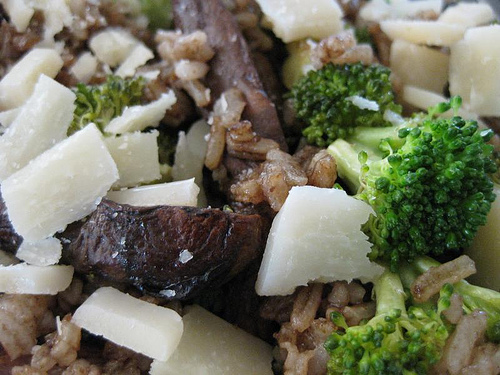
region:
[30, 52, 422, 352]
white chunks of food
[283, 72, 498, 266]
a piece of broccoli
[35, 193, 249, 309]
a piece of cooked meat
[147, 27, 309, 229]
pieces of brown rice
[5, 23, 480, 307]
a rice, meat and veggie dish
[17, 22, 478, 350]
food mixed together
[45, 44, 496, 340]
veggies and meat mixed together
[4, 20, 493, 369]
a rice dish with meat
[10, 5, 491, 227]
a rice dish with broccoli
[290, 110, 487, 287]
dark green cooked broccoli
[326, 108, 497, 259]
Whole peice of broccolli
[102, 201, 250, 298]
Peice of a mushroom top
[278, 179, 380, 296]
A peice of something white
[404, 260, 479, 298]
A small peice of rice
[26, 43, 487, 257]
A bunch of mixed vegetables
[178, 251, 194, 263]
White spot on the mushroom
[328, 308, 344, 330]
A single hair on the broccolli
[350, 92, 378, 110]
The white chunk on the broccollii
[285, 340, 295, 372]
The closest peice of rice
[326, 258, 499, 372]
The closest peice of broccollii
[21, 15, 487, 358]
a close up of food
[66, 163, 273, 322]
the dish has mean as an ingredient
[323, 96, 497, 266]
the dish contains a green vegetable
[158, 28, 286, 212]
the dish has rice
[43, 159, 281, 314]
the meat is sliced beef steak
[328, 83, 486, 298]
the green vegetable is broccoli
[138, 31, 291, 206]
the rice is brown in color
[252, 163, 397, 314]
a white vegetable is in the dish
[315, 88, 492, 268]
the broccoli is green in color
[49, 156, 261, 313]
sliced beef is in the rice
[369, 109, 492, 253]
piece of cooked green broccoli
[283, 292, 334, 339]
cooked brown rice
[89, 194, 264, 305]
piece of cooked beef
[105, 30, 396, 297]
cooked rice and vegetable dish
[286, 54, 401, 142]
cooked green broccoli floret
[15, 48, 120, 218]
pieces of cooked water chestnuts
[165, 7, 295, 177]
piece of meat covered in cooked brown rice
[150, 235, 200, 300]
pieces of chestnut on cooked beef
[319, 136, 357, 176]
green stem on cooked broccoli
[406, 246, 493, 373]
brown rice laying on broccoli piece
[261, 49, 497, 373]
pieces of broccoli on right side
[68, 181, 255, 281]
piece of meat in the foreground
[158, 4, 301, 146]
piece of meat in the background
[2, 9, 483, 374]
meat and vegetable stir fry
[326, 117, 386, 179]
stem of piece of broccoli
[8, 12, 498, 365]
brown rice mixed in with meat and vegetable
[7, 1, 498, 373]
white flecks in the stir fry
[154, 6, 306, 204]
rice covering piece of meat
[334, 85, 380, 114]
white fleck on green head of broccoli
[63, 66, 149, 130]
piece of broccoli on the left side